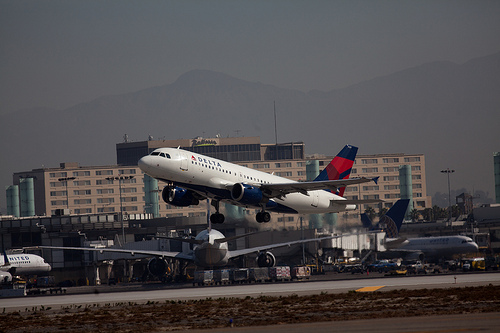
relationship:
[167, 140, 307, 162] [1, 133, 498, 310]
tower of airport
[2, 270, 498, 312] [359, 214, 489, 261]
runway lined with planes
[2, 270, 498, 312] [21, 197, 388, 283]
runway lined with planes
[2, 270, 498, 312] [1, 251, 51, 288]
runway lined with planes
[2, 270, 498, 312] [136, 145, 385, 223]
runway lined with planes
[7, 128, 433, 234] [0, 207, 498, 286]
building near airport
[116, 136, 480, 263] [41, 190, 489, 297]
plane at gate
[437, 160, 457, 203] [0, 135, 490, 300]
lights to guide planes